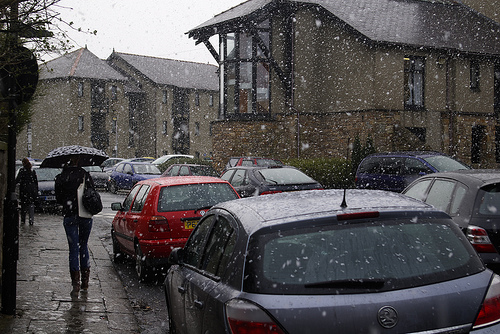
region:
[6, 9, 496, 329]
a rainy beautiful day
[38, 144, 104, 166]
a black umbrella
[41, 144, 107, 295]
a woman walking on the street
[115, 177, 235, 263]
a red car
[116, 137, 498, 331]
many cars in the street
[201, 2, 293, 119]
a wooden balcony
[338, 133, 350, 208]
the antenna car radio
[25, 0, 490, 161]
three beautiful houses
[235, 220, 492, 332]
the rear view of the car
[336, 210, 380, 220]
the red stop light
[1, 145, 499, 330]
Snow is falling on the cars.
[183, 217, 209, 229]
The license plate is partly hidden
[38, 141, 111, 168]
The umbrella is covered in snow.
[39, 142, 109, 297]
A woman holding an umbrella is walking.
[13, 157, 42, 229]
A woman is walking in the snow.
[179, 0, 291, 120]
The window has a roof over it.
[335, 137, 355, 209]
Black antenna on car roof.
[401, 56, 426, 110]
A light is on inside the window.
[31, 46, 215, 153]
The building id divided in the middle with a setback.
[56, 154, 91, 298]
The woman is wearing boots.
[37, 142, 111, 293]
a woman walking under an umbrella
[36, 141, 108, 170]
an umbrella over the woman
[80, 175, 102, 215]
a purse carried by the woman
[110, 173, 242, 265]
a red car next to the woman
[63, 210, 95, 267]
blue jeans on the woman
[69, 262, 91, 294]
jeans on the woman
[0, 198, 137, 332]
a sidewalk next to the street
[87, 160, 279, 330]
a crowded city street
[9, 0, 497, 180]
buildings behind the street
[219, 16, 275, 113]
large windows on the building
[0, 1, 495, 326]
It is snowing outside.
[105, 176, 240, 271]
The car is red.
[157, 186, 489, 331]
The car is blue.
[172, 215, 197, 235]
The license plate is yellow.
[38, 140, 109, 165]
The umbrella is black.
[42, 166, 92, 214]
Her jacket is black.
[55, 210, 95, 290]
Her pants are black.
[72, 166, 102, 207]
Her purse is black.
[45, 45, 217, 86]
The roof is brown.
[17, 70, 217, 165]
The building is tan.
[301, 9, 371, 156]
snow falling to the ground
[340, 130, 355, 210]
antenna on the back of the car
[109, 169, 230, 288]
red car parked by the curb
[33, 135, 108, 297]
person walking with an umbrella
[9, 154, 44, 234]
person walking down the sidewalk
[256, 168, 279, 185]
windshield wiper on back of car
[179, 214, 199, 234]
yellow license plate on red car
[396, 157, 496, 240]
car driving down the road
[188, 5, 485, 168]
building across the street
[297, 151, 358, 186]
bushes growing next to the building